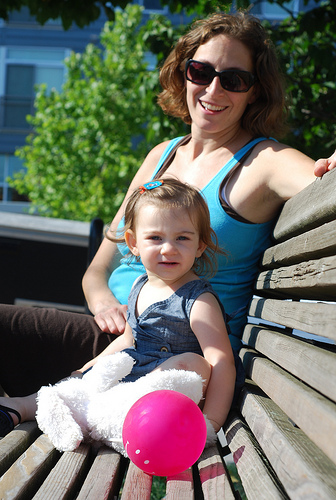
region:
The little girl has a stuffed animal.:
[35, 169, 236, 486]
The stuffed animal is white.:
[20, 343, 222, 474]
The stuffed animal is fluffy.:
[27, 344, 211, 482]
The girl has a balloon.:
[107, 377, 224, 486]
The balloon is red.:
[112, 385, 215, 486]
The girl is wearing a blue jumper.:
[101, 266, 229, 420]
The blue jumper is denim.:
[112, 273, 224, 393]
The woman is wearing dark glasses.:
[174, 54, 263, 105]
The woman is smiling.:
[189, 99, 241, 116]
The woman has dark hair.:
[144, 8, 315, 152]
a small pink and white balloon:
[123, 389, 207, 474]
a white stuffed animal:
[25, 351, 213, 466]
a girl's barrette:
[138, 181, 165, 194]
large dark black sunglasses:
[186, 57, 257, 95]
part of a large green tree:
[3, 7, 183, 216]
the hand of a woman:
[95, 302, 133, 334]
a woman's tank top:
[105, 129, 276, 366]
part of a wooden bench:
[1, 413, 334, 498]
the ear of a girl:
[125, 230, 138, 256]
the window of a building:
[4, 63, 35, 126]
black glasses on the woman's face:
[183, 55, 258, 93]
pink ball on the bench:
[121, 388, 206, 478]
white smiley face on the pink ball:
[123, 437, 157, 475]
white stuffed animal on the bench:
[32, 352, 218, 453]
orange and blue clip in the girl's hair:
[138, 178, 167, 194]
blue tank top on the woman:
[108, 135, 274, 353]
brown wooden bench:
[0, 164, 335, 498]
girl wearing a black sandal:
[1, 402, 22, 437]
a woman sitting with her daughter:
[49, 13, 267, 421]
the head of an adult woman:
[124, 14, 276, 152]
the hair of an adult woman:
[171, 23, 201, 53]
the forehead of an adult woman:
[202, 33, 246, 65]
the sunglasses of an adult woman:
[187, 53, 249, 96]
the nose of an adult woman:
[196, 80, 227, 100]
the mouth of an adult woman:
[199, 91, 231, 115]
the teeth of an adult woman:
[209, 99, 218, 112]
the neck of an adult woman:
[181, 117, 231, 151]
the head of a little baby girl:
[121, 180, 205, 285]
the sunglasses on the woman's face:
[184, 59, 259, 93]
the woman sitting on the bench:
[0, 7, 334, 395]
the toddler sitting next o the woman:
[0, 179, 234, 446]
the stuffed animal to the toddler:
[34, 352, 217, 457]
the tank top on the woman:
[107, 133, 278, 352]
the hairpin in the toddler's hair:
[139, 180, 163, 193]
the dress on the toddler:
[82, 271, 231, 380]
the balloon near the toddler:
[122, 389, 206, 475]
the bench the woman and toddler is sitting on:
[0, 166, 335, 498]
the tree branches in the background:
[0, 0, 335, 223]